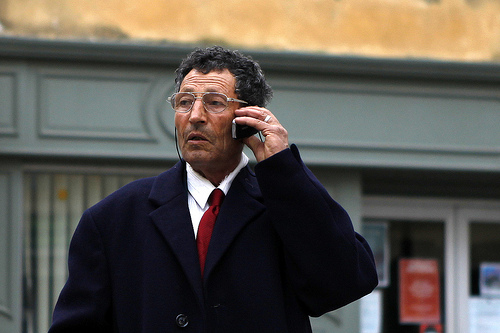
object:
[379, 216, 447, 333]
door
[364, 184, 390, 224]
ground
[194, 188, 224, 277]
tie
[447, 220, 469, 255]
glassdoor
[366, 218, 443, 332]
window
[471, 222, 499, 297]
window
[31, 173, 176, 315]
window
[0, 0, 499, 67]
wood work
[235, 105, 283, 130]
finger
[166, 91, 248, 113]
eye glasses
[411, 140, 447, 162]
ground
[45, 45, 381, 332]
main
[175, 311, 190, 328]
plastic button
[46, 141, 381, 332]
coat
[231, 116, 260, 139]
cellphone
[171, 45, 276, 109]
hair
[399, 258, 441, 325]
sign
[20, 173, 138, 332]
valence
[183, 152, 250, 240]
shirt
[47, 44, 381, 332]
he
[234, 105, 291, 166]
hand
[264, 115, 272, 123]
ring